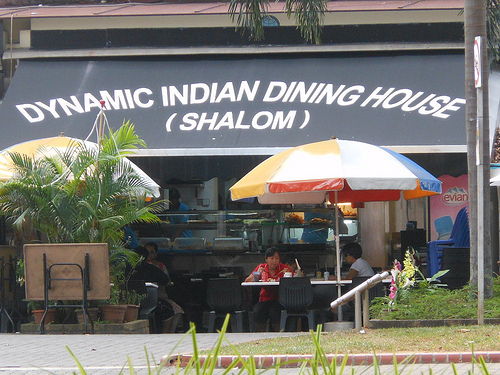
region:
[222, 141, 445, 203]
the umbrellas are multicolored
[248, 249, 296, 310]
woman in red shirt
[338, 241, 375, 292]
woman in white shirt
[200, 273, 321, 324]
two black plastic chairs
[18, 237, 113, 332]
table that is not unfolded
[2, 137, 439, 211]
two opened umbrellas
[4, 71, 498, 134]
black and white restaurant sign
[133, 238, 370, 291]
four people at restaurant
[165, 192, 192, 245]
man in blue shirt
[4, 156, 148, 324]
clay pots with palm trees in them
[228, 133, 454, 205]
umbrella outside a restaurant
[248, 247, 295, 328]
person at a table outside a restaurant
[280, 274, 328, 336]
plastic chair sitting near a table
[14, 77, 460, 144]
words on the awning of a restaurant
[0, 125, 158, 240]
leaves of a tree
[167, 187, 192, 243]
person working inside a restaurant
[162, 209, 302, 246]
display of food in a restaurant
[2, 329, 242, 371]
sidewalk outside a restaurant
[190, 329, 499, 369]
grass beside the sidewalk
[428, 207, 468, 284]
stack of blue plastic chairs on the side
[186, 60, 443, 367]
an outside umbrella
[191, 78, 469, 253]
red white blue orange umbrella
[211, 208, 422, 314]
two people sitting at a table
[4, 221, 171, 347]
a table folded up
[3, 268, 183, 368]
a lot of planters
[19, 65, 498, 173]
white lettering on the awning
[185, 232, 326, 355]
black chairs at the tables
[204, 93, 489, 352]
tall umbrella is open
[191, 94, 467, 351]
tall umbrella over table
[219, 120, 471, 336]
two people sitting under umbrella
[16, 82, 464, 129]
dynamic indian dining house shalom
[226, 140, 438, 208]
the umbrella is colorful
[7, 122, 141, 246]
the plants are green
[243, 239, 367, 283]
two people are eating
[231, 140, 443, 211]
the umbrella is yellow, white, blue, red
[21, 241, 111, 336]
the table is folded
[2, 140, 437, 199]
two umbrellas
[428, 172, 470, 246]
evian sign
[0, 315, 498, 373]
the grass is long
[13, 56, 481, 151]
a black awning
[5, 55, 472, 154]
a black and white business sign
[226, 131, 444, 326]
a colorful striped patio umbrella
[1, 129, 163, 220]
a colorful striped patio umbrella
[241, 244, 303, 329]
a man sitting at a patio table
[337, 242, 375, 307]
a woman sitting at a patio table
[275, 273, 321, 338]
a black patio chair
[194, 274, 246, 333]
a black patio chair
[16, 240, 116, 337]
a standing folding table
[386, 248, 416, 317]
pink and yellow flowers